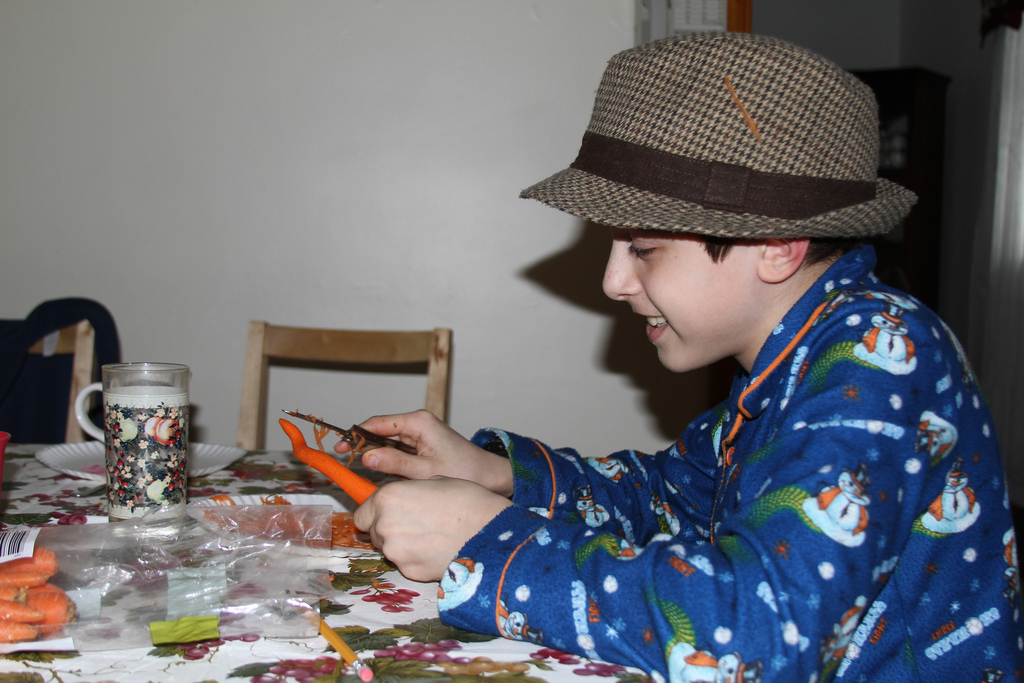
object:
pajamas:
[434, 260, 1024, 682]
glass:
[100, 361, 194, 539]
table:
[0, 429, 732, 682]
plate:
[36, 437, 250, 482]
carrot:
[277, 418, 382, 505]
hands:
[353, 471, 512, 582]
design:
[102, 394, 190, 523]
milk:
[104, 383, 187, 457]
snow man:
[802, 452, 874, 553]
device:
[281, 406, 417, 457]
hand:
[334, 407, 516, 496]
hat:
[514, 35, 925, 249]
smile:
[626, 299, 675, 350]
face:
[597, 218, 737, 375]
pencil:
[299, 584, 377, 682]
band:
[567, 131, 883, 222]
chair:
[236, 316, 454, 458]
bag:
[0, 499, 331, 656]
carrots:
[0, 566, 56, 590]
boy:
[338, 28, 1022, 682]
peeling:
[201, 490, 378, 551]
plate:
[177, 487, 379, 562]